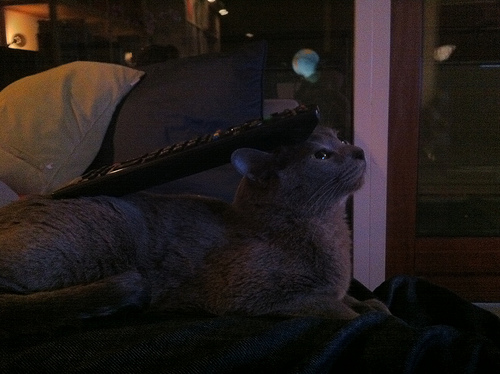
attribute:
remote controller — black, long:
[44, 99, 318, 199]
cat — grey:
[13, 109, 388, 319]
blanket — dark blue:
[29, 309, 479, 371]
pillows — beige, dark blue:
[1, 57, 272, 202]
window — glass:
[422, 16, 483, 230]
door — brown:
[389, 6, 478, 310]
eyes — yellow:
[312, 134, 351, 159]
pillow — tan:
[3, 60, 140, 190]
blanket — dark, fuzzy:
[21, 288, 434, 372]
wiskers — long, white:
[304, 171, 352, 228]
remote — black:
[52, 102, 318, 196]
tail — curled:
[11, 249, 141, 308]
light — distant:
[0, 9, 46, 52]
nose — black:
[334, 131, 391, 188]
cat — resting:
[34, 100, 381, 350]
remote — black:
[50, 115, 309, 194]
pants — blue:
[98, 297, 497, 363]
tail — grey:
[13, 235, 201, 359]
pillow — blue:
[115, 53, 272, 176]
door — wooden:
[351, 39, 498, 267]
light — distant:
[3, 9, 61, 74]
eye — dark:
[303, 131, 350, 166]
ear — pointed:
[212, 126, 321, 196]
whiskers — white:
[292, 181, 370, 224]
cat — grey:
[72, 142, 422, 336]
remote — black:
[47, 83, 363, 221]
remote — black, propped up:
[51, 95, 335, 195]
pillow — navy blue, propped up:
[79, 33, 269, 185]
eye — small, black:
[311, 146, 332, 164]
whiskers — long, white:
[302, 163, 371, 212]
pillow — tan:
[2, 61, 146, 204]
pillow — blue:
[117, 40, 288, 163]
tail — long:
[10, 261, 146, 340]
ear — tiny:
[226, 136, 287, 187]